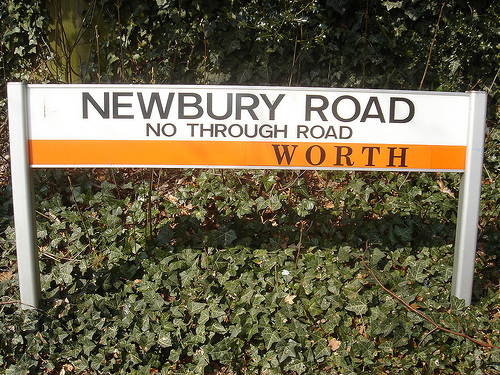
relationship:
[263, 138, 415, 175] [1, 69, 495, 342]
word on a sign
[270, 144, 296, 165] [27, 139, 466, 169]
letter on orange area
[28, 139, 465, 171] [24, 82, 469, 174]
stripe is on sign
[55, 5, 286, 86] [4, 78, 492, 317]
tree behind sign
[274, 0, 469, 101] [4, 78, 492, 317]
tree behind sign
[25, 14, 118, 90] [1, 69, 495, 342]
sticks behind sign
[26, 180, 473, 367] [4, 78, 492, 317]
leaves under sign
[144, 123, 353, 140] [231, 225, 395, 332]
letters spell no through to road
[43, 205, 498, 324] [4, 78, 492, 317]
shadow cast by sign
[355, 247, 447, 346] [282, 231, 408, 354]
twigs laying in greenery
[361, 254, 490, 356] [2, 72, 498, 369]
twigs popping out of ground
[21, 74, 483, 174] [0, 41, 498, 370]
sign in vegetation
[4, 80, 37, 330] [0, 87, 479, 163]
pole supporting sign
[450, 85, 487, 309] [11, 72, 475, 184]
right pole supporting sign